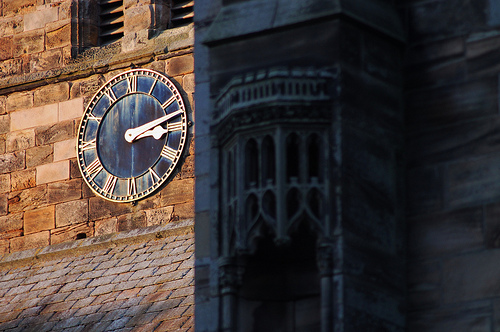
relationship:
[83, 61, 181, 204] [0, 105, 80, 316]
clock attached to wall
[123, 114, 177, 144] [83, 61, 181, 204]
hands attached to clock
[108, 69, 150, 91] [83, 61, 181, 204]
numerals on top of clock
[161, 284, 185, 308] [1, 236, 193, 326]
shingles on top of roof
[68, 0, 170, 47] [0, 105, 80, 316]
windows attached to wall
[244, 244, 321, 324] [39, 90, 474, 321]
entrance of building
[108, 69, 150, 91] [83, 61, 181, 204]
numerals attached to clock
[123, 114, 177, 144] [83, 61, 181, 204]
hands of clock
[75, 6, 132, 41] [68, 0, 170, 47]
shutters on top of windows